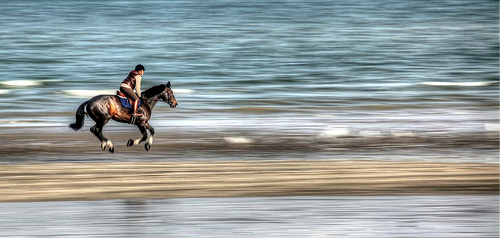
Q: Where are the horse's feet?
A: In the air.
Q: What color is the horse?
A: Black and white.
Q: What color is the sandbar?
A: Light brown.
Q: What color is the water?
A: Blue.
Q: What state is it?
A: North Carolina.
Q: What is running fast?
A: The horse and rider.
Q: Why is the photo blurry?
A: The horse is running fast.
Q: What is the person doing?
A: Riding a horse.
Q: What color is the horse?
A: Black.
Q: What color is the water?
A: Blue.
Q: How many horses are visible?
A: One.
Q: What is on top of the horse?
A: A female rider.